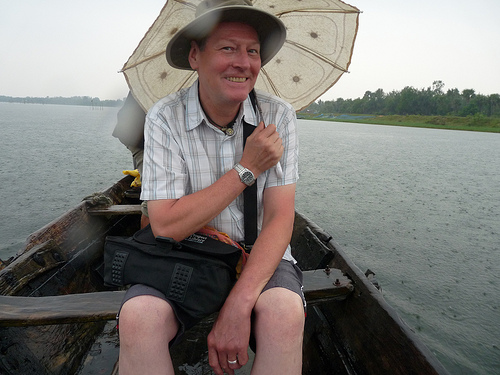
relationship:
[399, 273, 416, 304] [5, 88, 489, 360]
rain drops contacting water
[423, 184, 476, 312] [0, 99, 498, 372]
ripples on water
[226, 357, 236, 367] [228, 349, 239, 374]
wedding band on finger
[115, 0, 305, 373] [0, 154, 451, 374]
man sitting in boat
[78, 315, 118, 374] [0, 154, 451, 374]
water on boat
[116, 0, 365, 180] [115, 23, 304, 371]
umbrella shielding body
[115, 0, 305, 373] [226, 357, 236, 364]
man wearing ring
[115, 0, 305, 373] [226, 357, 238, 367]
man wearing ring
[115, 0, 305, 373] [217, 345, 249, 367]
man wearing ring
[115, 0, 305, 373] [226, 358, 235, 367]
man wearing wedding band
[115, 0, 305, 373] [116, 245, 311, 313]
man wearing shorts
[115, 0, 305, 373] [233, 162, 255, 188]
man wearing wrist watch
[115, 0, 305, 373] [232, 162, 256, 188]
man wearing watch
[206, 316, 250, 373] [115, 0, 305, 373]
hand of man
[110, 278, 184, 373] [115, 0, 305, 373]
leg of man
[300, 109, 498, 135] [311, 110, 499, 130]
grass on a field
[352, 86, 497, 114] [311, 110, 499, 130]
trees on a field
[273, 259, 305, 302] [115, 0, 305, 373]
shorts on a man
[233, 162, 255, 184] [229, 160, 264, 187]
wrist watch on a man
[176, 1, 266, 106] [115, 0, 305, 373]
head of a man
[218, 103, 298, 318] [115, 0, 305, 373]
arm of a man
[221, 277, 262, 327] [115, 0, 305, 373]
wrist of a man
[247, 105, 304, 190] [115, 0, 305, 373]
finger of a man